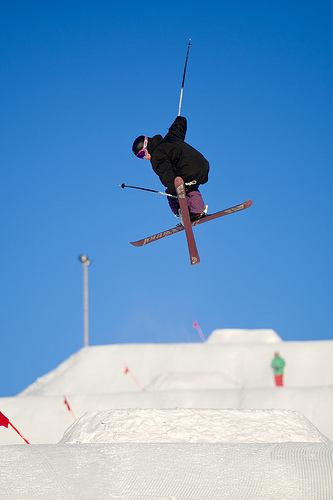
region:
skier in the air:
[97, 31, 285, 284]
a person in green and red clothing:
[261, 348, 294, 384]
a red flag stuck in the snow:
[0, 409, 37, 448]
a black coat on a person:
[147, 114, 215, 199]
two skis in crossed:
[137, 185, 256, 265]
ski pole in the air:
[168, 33, 200, 126]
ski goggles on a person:
[134, 138, 149, 159]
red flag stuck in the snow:
[60, 397, 81, 426]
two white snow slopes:
[126, 395, 236, 462]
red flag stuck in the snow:
[188, 317, 207, 345]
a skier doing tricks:
[112, 34, 256, 269]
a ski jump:
[197, 323, 287, 347]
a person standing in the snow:
[267, 349, 290, 388]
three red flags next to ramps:
[0, 360, 151, 448]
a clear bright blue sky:
[2, 5, 321, 341]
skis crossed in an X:
[127, 174, 252, 268]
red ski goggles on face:
[130, 133, 154, 160]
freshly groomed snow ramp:
[13, 442, 323, 495]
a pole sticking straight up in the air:
[171, 34, 196, 117]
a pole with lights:
[75, 251, 95, 353]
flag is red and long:
[52, 376, 295, 488]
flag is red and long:
[51, 388, 81, 421]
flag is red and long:
[106, 344, 173, 417]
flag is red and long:
[33, 367, 87, 437]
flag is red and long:
[49, 367, 111, 445]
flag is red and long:
[112, 361, 148, 404]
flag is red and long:
[51, 390, 96, 431]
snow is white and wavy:
[43, 362, 289, 490]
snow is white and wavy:
[67, 403, 262, 471]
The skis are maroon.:
[130, 176, 256, 261]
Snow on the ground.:
[179, 349, 250, 428]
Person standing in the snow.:
[265, 346, 296, 388]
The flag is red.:
[0, 411, 40, 455]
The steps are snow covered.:
[16, 406, 329, 497]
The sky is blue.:
[115, 272, 178, 313]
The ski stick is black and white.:
[119, 175, 177, 217]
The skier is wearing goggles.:
[128, 150, 164, 161]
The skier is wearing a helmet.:
[124, 130, 149, 156]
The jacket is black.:
[149, 136, 206, 196]